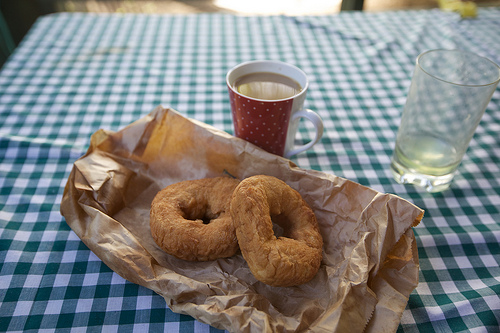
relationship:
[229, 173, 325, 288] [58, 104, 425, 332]
donut on top of paper bag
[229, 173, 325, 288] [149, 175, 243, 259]
donut next to donut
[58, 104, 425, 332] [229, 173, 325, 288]
paper bag has donut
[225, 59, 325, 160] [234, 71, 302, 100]
cup has coffee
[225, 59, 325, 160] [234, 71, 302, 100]
cup full of coffee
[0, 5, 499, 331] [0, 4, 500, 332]
table cloth covering table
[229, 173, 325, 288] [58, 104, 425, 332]
donut sitting on paper bag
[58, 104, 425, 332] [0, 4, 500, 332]
paper bag sitting on table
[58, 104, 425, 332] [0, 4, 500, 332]
paper bag laying on table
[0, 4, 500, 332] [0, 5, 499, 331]
table with table cloth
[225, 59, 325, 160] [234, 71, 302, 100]
cup with coffee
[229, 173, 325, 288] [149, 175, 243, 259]
donut by donut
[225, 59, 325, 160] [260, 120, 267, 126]
cup has polka dot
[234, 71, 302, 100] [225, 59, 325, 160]
coffee inside of cup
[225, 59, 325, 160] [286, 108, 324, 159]
cup has handle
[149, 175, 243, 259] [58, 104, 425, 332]
donut laying on paper bag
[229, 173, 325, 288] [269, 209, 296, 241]
donut has hole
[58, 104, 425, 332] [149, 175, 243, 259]
paper bag under donut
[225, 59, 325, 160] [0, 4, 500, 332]
cup sitting on table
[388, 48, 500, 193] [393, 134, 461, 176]
drinking glass with liquid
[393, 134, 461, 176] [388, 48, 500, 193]
liquid inside of drinking glass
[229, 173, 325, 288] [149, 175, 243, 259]
donut over donut